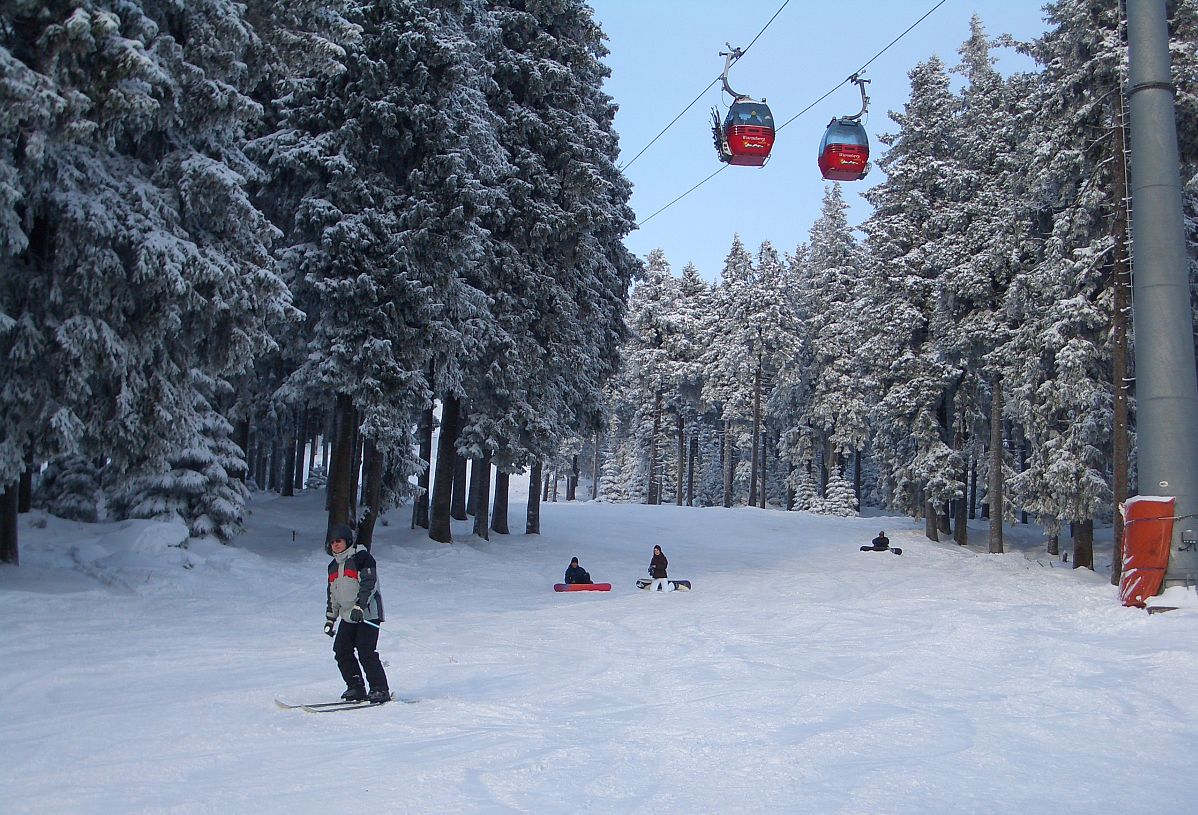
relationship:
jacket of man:
[320, 549, 386, 631] [313, 522, 400, 706]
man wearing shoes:
[318, 525, 389, 699] [339, 676, 397, 705]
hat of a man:
[323, 517, 350, 547] [313, 522, 400, 706]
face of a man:
[329, 532, 344, 554] [306, 523, 389, 690]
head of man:
[325, 511, 354, 557] [296, 511, 393, 712]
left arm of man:
[342, 542, 377, 625] [322, 528, 393, 707]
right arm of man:
[318, 559, 340, 634] [313, 522, 400, 706]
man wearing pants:
[318, 525, 389, 699] [332, 621, 390, 701]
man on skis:
[322, 528, 393, 707] [270, 689, 422, 712]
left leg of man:
[359, 626, 389, 699] [318, 525, 389, 699]